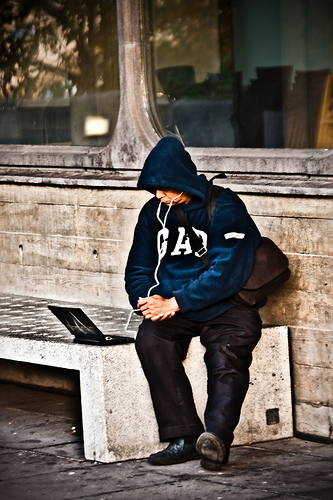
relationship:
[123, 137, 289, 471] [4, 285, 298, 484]
man sitting on bench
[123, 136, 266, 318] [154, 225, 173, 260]
hoodie with letter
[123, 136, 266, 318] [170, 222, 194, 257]
hoodie with letter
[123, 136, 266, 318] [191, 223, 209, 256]
hoodie with letter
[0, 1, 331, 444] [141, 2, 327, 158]
building has window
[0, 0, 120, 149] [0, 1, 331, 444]
window on building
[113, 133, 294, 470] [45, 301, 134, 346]
man looking at electronic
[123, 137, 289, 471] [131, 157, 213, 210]
man wearing hoodie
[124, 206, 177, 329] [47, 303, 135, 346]
cable plugged in electronic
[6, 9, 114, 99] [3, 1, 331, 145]
reflection on window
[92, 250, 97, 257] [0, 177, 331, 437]
hole in wall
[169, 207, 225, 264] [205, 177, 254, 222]
strap over shoulder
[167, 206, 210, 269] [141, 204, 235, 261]
strap across chest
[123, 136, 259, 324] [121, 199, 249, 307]
hoodie has sleeves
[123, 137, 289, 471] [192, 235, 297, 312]
man wears satchel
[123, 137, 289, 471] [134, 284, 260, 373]
man wears pants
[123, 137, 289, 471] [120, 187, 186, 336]
man wears headphones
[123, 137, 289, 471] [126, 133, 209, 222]
man has head